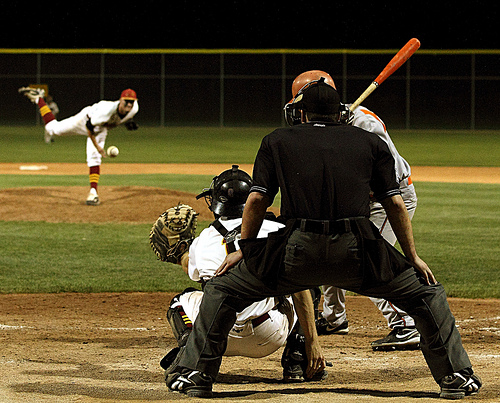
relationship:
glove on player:
[150, 202, 195, 264] [150, 164, 323, 382]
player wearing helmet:
[150, 164, 323, 382] [208, 167, 255, 218]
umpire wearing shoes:
[159, 363, 482, 402] [165, 361, 489, 402]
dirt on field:
[0, 289, 499, 402] [3, 124, 496, 402]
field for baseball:
[3, 124, 496, 402] [2, 2, 498, 399]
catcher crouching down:
[150, 164, 323, 382] [148, 322, 357, 395]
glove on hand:
[150, 202, 195, 264] [302, 337, 326, 378]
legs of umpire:
[169, 226, 469, 397] [159, 363, 482, 402]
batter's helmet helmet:
[282, 36, 424, 350] [280, 69, 340, 111]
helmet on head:
[280, 69, 340, 111] [287, 69, 345, 113]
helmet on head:
[208, 167, 255, 218] [205, 167, 255, 220]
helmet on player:
[208, 167, 255, 218] [150, 164, 323, 382]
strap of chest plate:
[212, 216, 246, 254] [262, 211, 280, 224]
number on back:
[360, 105, 390, 138] [344, 102, 409, 186]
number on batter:
[360, 105, 390, 138] [282, 36, 424, 350]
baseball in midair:
[108, 146, 119, 159] [109, 141, 133, 166]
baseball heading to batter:
[108, 146, 119, 159] [282, 36, 424, 350]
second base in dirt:
[20, 160, 49, 173] [0, 160, 499, 186]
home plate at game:
[262, 313, 348, 373] [2, 2, 494, 402]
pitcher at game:
[20, 84, 141, 204] [2, 2, 494, 402]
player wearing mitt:
[150, 164, 323, 382] [150, 202, 195, 264]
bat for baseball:
[342, 37, 422, 125] [2, 2, 498, 399]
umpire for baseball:
[159, 363, 482, 402] [2, 2, 498, 399]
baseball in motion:
[108, 146, 119, 159] [102, 145, 126, 158]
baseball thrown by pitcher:
[108, 146, 119, 159] [20, 84, 141, 204]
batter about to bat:
[282, 36, 424, 350] [342, 37, 422, 125]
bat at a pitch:
[342, 37, 422, 125] [80, 111, 126, 164]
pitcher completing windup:
[20, 84, 141, 204] [81, 110, 108, 151]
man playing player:
[150, 164, 323, 382] [150, 164, 323, 382]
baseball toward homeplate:
[2, 2, 498, 399] [322, 333, 349, 356]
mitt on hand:
[150, 202, 195, 264] [167, 227, 194, 264]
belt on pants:
[289, 213, 364, 235] [173, 215, 472, 384]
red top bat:
[373, 37, 420, 88] [342, 37, 422, 125]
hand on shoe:
[302, 337, 326, 378] [282, 342, 331, 384]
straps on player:
[212, 216, 246, 254] [150, 164, 323, 382]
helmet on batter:
[280, 69, 340, 111] [282, 36, 424, 350]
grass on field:
[2, 121, 499, 297] [3, 124, 496, 402]